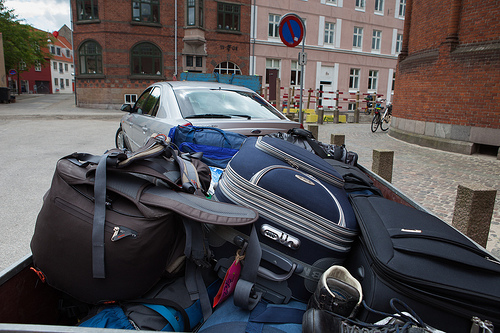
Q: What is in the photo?
A: Bags.